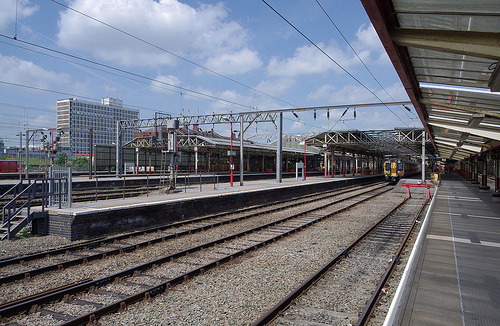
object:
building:
[55, 95, 141, 170]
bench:
[399, 182, 432, 199]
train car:
[382, 154, 424, 185]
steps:
[0, 175, 50, 239]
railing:
[32, 176, 68, 210]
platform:
[386, 166, 500, 325]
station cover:
[361, 2, 497, 164]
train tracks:
[4, 178, 432, 325]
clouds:
[55, 4, 264, 76]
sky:
[0, 0, 419, 137]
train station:
[1, 2, 497, 324]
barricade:
[320, 159, 400, 177]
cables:
[2, 1, 416, 136]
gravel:
[0, 182, 358, 309]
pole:
[271, 108, 284, 184]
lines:
[425, 182, 499, 323]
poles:
[224, 123, 314, 182]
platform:
[38, 168, 383, 215]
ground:
[0, 165, 499, 325]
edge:
[65, 196, 176, 215]